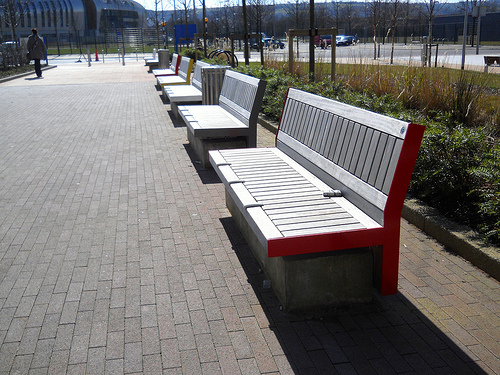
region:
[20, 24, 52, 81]
person walking on the sidewalk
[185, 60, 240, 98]
trash can in the park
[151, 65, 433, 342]
benches on the pavilion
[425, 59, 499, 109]
flowers growing in the wilderness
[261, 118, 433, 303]
Red paint on the side of a bench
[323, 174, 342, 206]
lock on a bench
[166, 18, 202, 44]
blue sign on the pole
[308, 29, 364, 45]
cars parked in the lot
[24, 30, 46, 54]
person wearing a green jacket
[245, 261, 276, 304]
debris under the bench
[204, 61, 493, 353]
a row of beneches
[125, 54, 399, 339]
a row of benches outside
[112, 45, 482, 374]
benches on the sidewalk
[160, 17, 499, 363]
row of bench on the sidewalk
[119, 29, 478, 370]
benches that are outside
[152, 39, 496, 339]
row of benches outside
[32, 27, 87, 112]
a person walking otuside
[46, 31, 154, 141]
a person walkin gon the sidewal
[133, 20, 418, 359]
a sidewalk with benches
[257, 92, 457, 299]
a bench with a red side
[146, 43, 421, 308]
a row of benches sits on the pathway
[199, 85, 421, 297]
the bench is made of wood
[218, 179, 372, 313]
a block of concrete is under the bench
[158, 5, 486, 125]
trees are planted behind the benches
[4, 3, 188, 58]
a stadium is in the background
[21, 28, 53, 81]
a person is walking down the pathway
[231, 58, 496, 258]
green plants are planted behind the benches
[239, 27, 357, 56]
a few vehicles are in the lot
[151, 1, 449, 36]
a mountain can be seen in the far distance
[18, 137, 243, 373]
the pathway is made of stone bricks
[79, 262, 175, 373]
Bricks on the walkway.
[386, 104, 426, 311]
The red side of the bench.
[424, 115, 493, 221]
Bushes behind the bench.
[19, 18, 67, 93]
A person walking down the street.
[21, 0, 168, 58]
A building in the background.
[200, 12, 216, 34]
A stoplight in the background.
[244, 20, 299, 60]
A car in the background.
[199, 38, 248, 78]
An empty bike rack.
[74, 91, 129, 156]
Brick on the walkway.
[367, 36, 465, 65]
The street for cars to drive on.